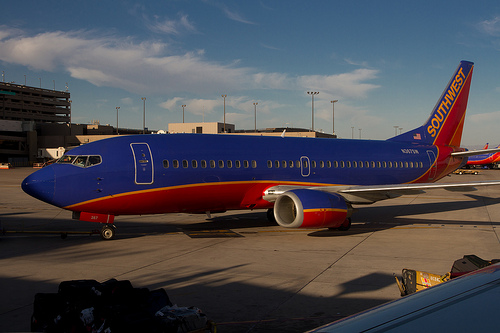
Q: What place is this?
A: It is an airport.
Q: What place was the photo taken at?
A: It was taken at the airport.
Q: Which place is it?
A: It is an airport.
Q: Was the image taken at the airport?
A: Yes, it was taken in the airport.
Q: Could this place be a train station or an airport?
A: It is an airport.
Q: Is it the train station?
A: No, it is the airport.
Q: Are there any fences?
A: No, there are no fences.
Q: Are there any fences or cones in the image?
A: No, there are no fences or cones.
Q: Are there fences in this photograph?
A: No, there are no fences.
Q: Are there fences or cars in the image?
A: No, there are no fences or cars.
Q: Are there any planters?
A: No, there are no planters.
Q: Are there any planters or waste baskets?
A: No, there are no planters or waste baskets.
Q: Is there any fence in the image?
A: No, there are no fences.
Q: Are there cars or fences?
A: No, there are no fences or cars.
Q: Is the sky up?
A: Yes, the sky is up.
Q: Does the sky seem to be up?
A: Yes, the sky is up.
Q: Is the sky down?
A: No, the sky is up.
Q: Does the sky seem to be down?
A: No, the sky is up.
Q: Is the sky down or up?
A: The sky is up.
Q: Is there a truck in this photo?
A: No, there are no trucks.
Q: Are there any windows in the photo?
A: Yes, there are windows.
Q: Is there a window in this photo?
A: Yes, there are windows.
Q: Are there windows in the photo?
A: Yes, there are windows.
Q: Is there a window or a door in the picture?
A: Yes, there are windows.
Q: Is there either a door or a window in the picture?
A: Yes, there are windows.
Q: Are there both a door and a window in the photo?
A: Yes, there are both a window and a door.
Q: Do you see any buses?
A: No, there are no buses.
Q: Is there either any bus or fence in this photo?
A: No, there are no buses or fences.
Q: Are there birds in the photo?
A: No, there are no birds.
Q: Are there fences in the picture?
A: No, there are no fences.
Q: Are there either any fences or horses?
A: No, there are no fences or horses.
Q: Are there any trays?
A: No, there are no trays.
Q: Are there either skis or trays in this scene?
A: No, there are no trays or skis.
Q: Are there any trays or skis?
A: No, there are no trays or skis.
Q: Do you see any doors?
A: Yes, there is a door.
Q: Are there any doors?
A: Yes, there is a door.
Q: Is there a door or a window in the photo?
A: Yes, there is a door.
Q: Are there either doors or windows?
A: Yes, there is a door.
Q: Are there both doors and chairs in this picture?
A: No, there is a door but no chairs.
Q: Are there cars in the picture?
A: No, there are no cars.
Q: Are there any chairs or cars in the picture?
A: No, there are no cars or chairs.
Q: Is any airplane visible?
A: Yes, there is an airplane.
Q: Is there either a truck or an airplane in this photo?
A: Yes, there is an airplane.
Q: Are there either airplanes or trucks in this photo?
A: Yes, there is an airplane.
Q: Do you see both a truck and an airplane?
A: No, there is an airplane but no trucks.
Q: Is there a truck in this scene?
A: No, there are no trucks.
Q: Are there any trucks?
A: No, there are no trucks.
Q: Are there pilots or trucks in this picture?
A: No, there are no trucks or pilots.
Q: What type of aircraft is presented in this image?
A: The aircraft is an airplane.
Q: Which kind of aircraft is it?
A: The aircraft is an airplane.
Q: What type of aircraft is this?
A: This is an airplane.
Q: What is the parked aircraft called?
A: The aircraft is an airplane.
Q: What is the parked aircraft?
A: The aircraft is an airplane.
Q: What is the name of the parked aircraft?
A: The aircraft is an airplane.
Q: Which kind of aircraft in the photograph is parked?
A: The aircraft is an airplane.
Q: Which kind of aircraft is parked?
A: The aircraft is an airplane.